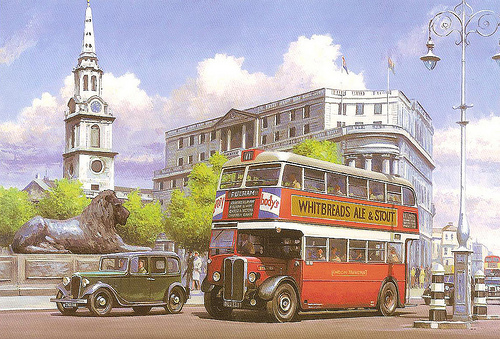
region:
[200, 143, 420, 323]
red double decker bus on a street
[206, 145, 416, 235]
upper level of a double decker bus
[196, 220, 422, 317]
lower level of a double decker bus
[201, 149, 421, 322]
double decker red bus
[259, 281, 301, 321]
black front bus wheel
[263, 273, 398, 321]
two wheels of a bus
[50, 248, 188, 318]
old fashion green vehicle on a street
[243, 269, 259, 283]
headlight of a bus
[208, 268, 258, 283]
two round white bus lights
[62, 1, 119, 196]
tall white tower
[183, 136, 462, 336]
a double decker bus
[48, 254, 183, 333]
a green vintage car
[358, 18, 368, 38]
The sky is a very bright blue color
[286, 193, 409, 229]
The bus has a placard that has orange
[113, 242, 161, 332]
This car is very dark green in color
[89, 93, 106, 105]
There is a clock tower here that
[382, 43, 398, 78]
There is an American flag that is visible here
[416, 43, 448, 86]
There is a lamp that is visible here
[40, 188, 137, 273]
There is a brown lion that is visible here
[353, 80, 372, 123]
There is a white building that is visible here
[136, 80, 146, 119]
There are some white puffy clouds visible here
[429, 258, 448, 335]
There is a small tower that is white and brown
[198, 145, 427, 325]
red double decker bus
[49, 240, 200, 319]
green car with gray roof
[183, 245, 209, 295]
couple walking along street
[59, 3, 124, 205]
white stone tower building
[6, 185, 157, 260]
statue of a lion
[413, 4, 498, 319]
metal street lamp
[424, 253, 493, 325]
black and white pylons by base of lamp post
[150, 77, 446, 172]
large white building in background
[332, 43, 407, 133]
two flags on building balcony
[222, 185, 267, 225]
destination placard on bus